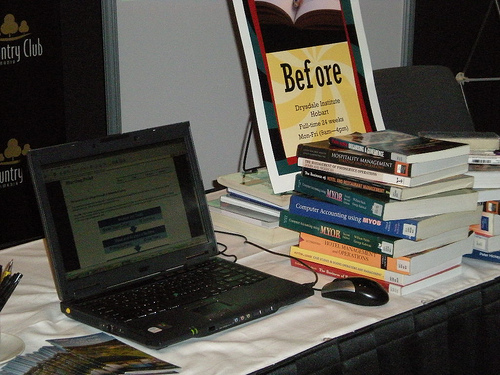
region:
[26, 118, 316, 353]
Open laptop computer.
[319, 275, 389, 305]
Black and silver computer mouse.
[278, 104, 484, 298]
Stack of ten books.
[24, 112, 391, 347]
Black laptop computer and mouse.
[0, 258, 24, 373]
Container of pens.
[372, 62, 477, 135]
Fabric covered chair.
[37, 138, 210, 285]
Laptop computer screen with an image displayed.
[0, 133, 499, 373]
Table covered with a white linen cloth.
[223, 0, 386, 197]
Sign saying "Before" displayed on easel.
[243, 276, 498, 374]
Dark colored, pleated table skirt.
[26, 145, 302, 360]
black older model laptop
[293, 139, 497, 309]
stack of college books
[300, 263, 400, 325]
black computer mouse with wire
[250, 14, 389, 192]
sign that says before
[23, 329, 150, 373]
stack of organized pamphlets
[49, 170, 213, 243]
dimmed down computer screen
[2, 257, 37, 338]
pens in a pen holder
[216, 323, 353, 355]
white table top cover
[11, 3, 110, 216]
framed art black board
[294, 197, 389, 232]
computer accounting text book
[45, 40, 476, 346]
books and laptop on table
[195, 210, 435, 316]
computer mouse between laptop and books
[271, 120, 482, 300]
soft-cover books stacked in a pile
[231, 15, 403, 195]
upright sign behind books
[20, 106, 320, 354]
laptop turned on and displaying text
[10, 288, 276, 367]
brochures fanned out next to laptop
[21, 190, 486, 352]
white tablecloth covering display table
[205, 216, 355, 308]
black wire connecting mouse to computer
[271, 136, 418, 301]
titles of books about business management and accounting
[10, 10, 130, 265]
poster on wall behind laptop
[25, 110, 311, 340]
A laptop on a desk.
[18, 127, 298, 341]
The laptop is open.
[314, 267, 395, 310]
A black computer mouse.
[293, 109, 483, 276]
A stack of books.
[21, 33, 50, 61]
The word club in white lettering.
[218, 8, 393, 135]
A square sign.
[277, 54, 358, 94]
The word Before on a sign.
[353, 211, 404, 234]
The letters MYOB on a book.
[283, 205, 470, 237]
A book with a blue covering.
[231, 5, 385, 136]
A sign with a white border.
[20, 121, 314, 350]
an open laptop computer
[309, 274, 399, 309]
a computer mouse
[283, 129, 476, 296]
a stack of paperback books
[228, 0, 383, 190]
an advertisement poster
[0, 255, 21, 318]
some pens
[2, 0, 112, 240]
a poster on a wall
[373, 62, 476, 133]
the back of a chair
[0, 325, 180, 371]
several booklets used as handouts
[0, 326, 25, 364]
a white ceramic plate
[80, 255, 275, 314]
a laptop's keyboard